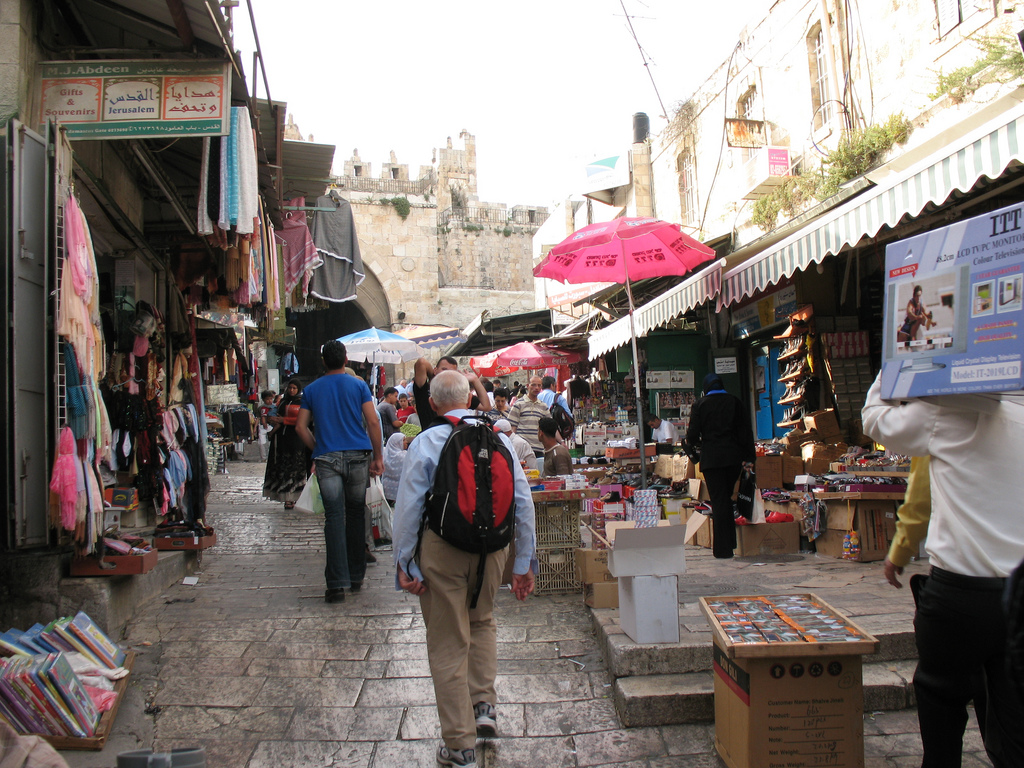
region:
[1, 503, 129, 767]
items for sale on the ground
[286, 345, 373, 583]
a man in a blue t shirt walking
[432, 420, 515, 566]
the bag pack is red and black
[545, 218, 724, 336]
the umbrella is pink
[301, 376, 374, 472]
the man's t-shirt is blue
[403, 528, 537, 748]
old man's slacks is brown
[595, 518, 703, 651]
boxes are white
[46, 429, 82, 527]
the scarf is pink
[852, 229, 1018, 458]
the man is carrying a box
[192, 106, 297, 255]
scarfs are hanging by the roof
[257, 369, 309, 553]
the woman is walking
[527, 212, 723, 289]
an open pink umbrella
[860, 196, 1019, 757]
man carrying box on his shloulder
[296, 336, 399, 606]
man walking with a shopping bag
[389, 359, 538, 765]
man with a red and black backpack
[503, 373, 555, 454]
man in a striped shirt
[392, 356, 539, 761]
man wearing khaki pants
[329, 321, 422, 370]
a blue and white umbrella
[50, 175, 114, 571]
clothing for sale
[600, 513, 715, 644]
white cardboard boxes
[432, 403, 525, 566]
red and black backpack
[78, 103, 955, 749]
outdoor street market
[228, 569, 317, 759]
brick pavement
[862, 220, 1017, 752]
a person carrying a box on his shoulder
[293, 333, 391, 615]
a man wearing a blue shirt and jeans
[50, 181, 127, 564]
a display of scarves for sale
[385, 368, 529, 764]
a man wearing a blue shirt and tan pants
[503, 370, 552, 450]
a man wearing a striped shirt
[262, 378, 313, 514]
a woman wearing a skirt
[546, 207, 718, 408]
open umbrella in market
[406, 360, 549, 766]
man wearing a backpack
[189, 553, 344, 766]
stone paved walkway in market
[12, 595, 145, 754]
packages for sale in market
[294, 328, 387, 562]
man in a blue shirt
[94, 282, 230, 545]
clothes for sale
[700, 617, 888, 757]
cardboard box on the ground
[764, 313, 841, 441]
shoes for sale in a market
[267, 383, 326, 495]
woman in a dress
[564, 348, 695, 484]
assorted items for sale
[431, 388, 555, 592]
A red and black backpack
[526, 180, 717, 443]
A pink umbrella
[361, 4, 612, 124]
Sky is overcast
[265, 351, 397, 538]
Person wearing a blue shirt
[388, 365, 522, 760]
Man wearing beige pants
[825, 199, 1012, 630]
Person is holding up a big box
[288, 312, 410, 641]
Person is wearing blue jeans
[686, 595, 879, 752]
A brown carton box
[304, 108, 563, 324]
Building in the background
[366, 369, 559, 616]
Man has on a light blue shirt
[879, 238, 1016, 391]
a box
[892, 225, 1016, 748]
someone is carrying a box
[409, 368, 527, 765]
a man has a backpack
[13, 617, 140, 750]
a stack of old records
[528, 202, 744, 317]
a pink umbrella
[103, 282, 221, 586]
items of clothing on a rack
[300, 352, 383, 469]
person has on blue t-shirt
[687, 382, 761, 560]
person dressed in all black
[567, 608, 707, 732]
concrete steps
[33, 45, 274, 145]
a sign written in a foreign language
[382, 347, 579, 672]
Man wearing red and black backpack